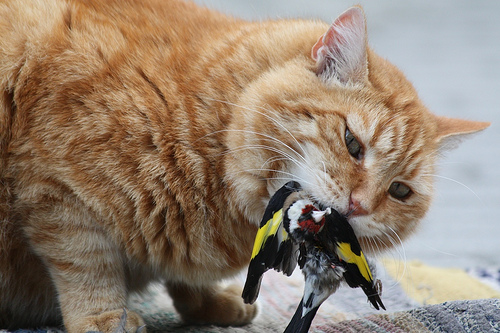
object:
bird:
[242, 180, 387, 333]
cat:
[0, 0, 492, 332]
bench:
[2, 264, 499, 333]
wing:
[239, 186, 290, 305]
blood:
[298, 204, 327, 234]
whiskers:
[195, 86, 329, 198]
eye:
[343, 123, 364, 163]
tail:
[282, 289, 332, 333]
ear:
[310, 4, 368, 86]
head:
[285, 202, 333, 242]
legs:
[15, 176, 258, 332]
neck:
[204, 15, 305, 243]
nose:
[344, 187, 379, 219]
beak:
[311, 203, 333, 222]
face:
[289, 200, 328, 239]